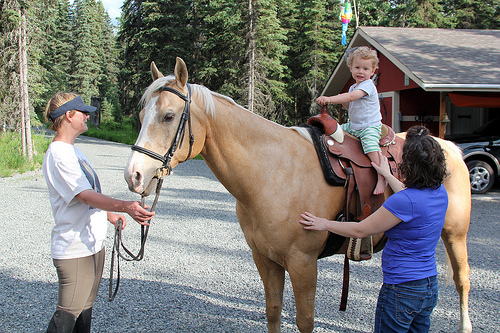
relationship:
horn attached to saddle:
[322, 96, 330, 111] [310, 101, 411, 218]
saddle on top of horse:
[310, 101, 411, 218] [125, 56, 473, 332]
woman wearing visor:
[44, 91, 156, 333] [48, 94, 97, 120]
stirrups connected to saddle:
[346, 234, 376, 261] [310, 101, 411, 218]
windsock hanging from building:
[337, 1, 354, 46] [316, 26, 500, 147]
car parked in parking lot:
[454, 140, 500, 194] [0, 167, 499, 332]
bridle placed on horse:
[131, 75, 194, 177] [125, 56, 473, 332]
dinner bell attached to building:
[442, 113, 451, 135] [316, 26, 500, 147]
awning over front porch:
[450, 91, 500, 107] [399, 89, 499, 137]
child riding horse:
[314, 45, 393, 194] [125, 56, 473, 332]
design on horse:
[130, 95, 160, 165] [125, 56, 473, 332]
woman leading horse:
[44, 91, 156, 333] [125, 56, 473, 332]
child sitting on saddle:
[314, 45, 393, 194] [310, 101, 411, 218]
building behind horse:
[316, 26, 500, 147] [125, 56, 473, 332]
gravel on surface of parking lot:
[0, 172, 500, 332] [0, 167, 499, 332]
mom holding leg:
[300, 126, 450, 332] [360, 131, 392, 194]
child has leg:
[314, 45, 393, 194] [360, 131, 392, 194]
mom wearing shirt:
[300, 126, 450, 332] [381, 183, 449, 285]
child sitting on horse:
[314, 45, 393, 194] [125, 56, 473, 332]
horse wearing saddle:
[125, 56, 473, 332] [310, 101, 411, 218]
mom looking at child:
[300, 126, 450, 332] [314, 45, 393, 194]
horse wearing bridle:
[125, 56, 473, 332] [131, 75, 194, 177]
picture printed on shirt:
[78, 158, 101, 194] [44, 143, 111, 254]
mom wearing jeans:
[300, 126, 450, 332] [374, 277, 438, 332]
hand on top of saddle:
[317, 96, 330, 105] [310, 101, 411, 218]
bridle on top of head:
[131, 75, 194, 177] [125, 56, 209, 198]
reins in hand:
[109, 177, 163, 300] [109, 212, 126, 229]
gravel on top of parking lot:
[0, 172, 500, 332] [0, 167, 499, 332]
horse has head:
[125, 56, 473, 332] [125, 56, 209, 198]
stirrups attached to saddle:
[346, 234, 376, 261] [310, 101, 411, 218]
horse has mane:
[125, 56, 473, 332] [141, 73, 218, 121]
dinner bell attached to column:
[442, 113, 451, 135] [438, 91, 448, 139]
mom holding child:
[300, 126, 450, 332] [314, 45, 393, 194]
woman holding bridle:
[44, 91, 156, 333] [131, 75, 194, 177]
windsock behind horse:
[337, 1, 354, 46] [125, 56, 473, 332]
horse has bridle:
[125, 56, 473, 332] [131, 75, 194, 177]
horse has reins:
[125, 56, 473, 332] [109, 177, 163, 300]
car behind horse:
[454, 140, 500, 194] [125, 56, 473, 332]